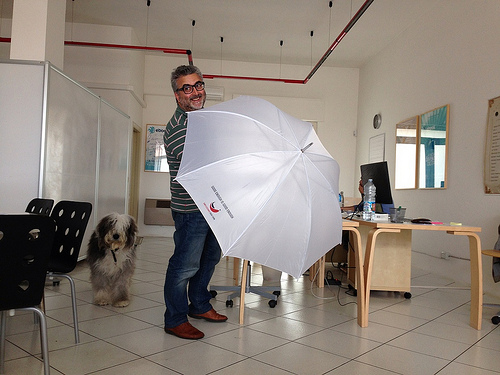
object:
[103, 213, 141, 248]
head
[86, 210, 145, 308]
dog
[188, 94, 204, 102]
mouth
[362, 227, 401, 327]
leg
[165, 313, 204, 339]
shoe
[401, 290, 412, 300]
wheel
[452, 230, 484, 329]
leg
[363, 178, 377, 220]
bottle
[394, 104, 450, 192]
sign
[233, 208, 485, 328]
desk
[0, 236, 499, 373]
floor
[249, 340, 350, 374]
tile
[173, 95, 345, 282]
umbrella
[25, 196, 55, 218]
chair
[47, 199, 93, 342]
chair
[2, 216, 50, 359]
chair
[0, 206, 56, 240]
table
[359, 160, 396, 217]
computer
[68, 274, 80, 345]
leg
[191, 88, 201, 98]
nose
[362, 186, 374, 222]
water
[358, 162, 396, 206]
screen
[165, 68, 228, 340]
man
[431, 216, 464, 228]
posted notes